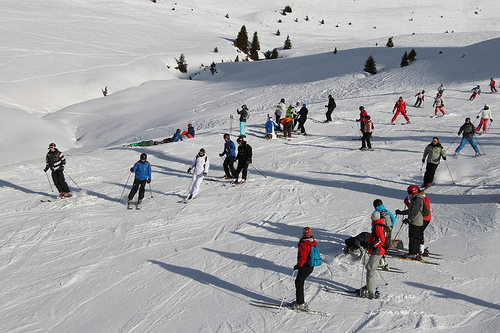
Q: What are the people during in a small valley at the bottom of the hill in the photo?
A: Ice skating.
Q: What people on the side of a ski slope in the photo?
A: People wearing red, grey, black and blue.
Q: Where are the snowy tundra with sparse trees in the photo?
A: Back of the skiers.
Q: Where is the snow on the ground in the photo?
A: Everywhere.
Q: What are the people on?
A: Snow.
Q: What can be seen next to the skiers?
A: Their shadows.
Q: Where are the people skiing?
A: Mountain.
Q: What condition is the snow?
A: Freshly fallen.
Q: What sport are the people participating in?
A: Downhill skiing.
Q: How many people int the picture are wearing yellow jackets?
A: 0.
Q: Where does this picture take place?
A: A downhill ski hill.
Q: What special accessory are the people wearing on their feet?
A: Skis.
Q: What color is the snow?
A: White.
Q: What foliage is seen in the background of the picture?
A: Trees.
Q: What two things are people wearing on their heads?
A: Hats and helmets.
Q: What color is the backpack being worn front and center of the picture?
A: Blue.